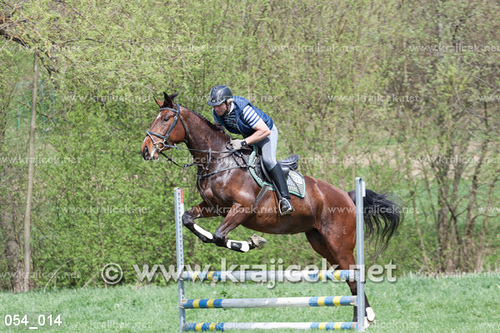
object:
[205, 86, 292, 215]
man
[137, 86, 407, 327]
horse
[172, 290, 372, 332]
hurdle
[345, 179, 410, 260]
tail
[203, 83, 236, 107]
helmet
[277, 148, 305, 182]
saddle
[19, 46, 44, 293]
trunk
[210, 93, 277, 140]
vest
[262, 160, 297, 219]
boot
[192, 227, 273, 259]
front legs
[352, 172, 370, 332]
pole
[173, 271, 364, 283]
pole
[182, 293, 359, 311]
pole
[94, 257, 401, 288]
watermark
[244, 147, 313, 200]
pad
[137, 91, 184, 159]
head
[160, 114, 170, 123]
eye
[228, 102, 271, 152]
left arm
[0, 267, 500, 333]
field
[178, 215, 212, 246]
guard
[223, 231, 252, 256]
guard